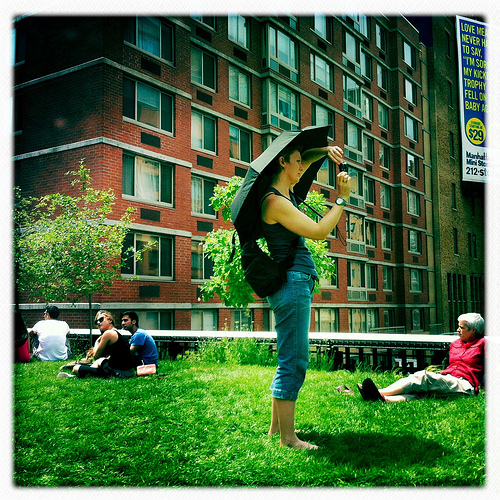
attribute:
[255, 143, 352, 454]
woman — young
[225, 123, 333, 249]
umbrella — black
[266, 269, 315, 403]
jeans — blue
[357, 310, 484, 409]
man — older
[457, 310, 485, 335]
hair — grey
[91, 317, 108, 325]
sunglasses — black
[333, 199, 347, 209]
wristwatch — green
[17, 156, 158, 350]
trees — green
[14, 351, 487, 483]
grass — green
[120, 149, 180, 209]
window — glass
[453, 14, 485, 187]
sign — in the air, advertising, blue, yellow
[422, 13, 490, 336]
building — large, tan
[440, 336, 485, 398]
shirt — red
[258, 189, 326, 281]
tshirt — black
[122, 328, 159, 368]
shirt — blue